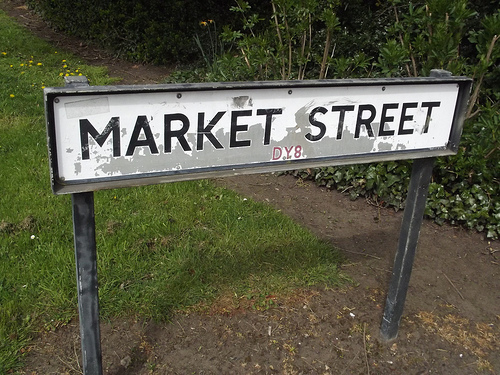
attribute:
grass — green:
[111, 194, 330, 290]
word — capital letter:
[80, 107, 283, 158]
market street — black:
[79, 101, 439, 159]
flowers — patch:
[19, 18, 391, 94]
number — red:
[294, 143, 301, 161]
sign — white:
[53, 81, 460, 174]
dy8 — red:
[263, 132, 325, 182]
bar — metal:
[67, 190, 104, 371]